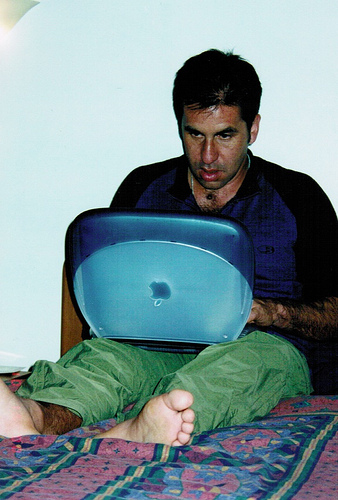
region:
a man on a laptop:
[0, 47, 335, 448]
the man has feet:
[0, 370, 198, 446]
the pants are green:
[20, 325, 314, 439]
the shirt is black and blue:
[90, 148, 337, 357]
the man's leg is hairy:
[35, 392, 86, 441]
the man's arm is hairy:
[253, 288, 337, 339]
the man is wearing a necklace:
[183, 149, 258, 205]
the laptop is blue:
[60, 201, 266, 350]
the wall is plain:
[0, 1, 333, 368]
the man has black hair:
[169, 44, 261, 147]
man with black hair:
[142, 45, 254, 158]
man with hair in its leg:
[36, 403, 76, 431]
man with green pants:
[64, 321, 265, 422]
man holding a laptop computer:
[61, 200, 260, 357]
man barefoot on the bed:
[79, 392, 204, 456]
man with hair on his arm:
[259, 281, 337, 333]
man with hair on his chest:
[194, 188, 233, 216]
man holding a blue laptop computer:
[57, 203, 260, 352]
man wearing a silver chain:
[180, 161, 202, 207]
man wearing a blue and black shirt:
[109, 162, 314, 243]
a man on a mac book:
[62, 30, 337, 365]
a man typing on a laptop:
[40, 51, 332, 317]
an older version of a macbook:
[26, 172, 313, 427]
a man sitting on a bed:
[66, 110, 337, 477]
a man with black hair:
[90, 56, 335, 309]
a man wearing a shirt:
[89, 47, 311, 328]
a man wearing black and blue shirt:
[101, 51, 335, 349]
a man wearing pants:
[26, 66, 333, 435]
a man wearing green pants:
[29, 52, 334, 432]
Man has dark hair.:
[168, 41, 258, 108]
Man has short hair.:
[179, 44, 277, 129]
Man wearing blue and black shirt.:
[258, 179, 312, 266]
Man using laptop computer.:
[78, 233, 259, 373]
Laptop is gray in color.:
[59, 222, 240, 334]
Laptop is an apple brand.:
[84, 222, 220, 327]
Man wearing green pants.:
[201, 349, 248, 401]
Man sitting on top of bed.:
[153, 362, 275, 492]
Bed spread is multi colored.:
[178, 391, 284, 498]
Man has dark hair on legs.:
[46, 408, 64, 423]